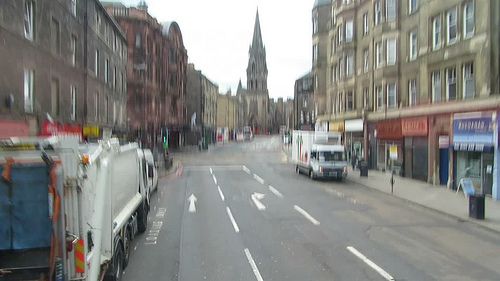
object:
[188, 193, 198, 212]
arrow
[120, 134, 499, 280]
road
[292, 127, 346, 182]
van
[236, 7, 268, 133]
building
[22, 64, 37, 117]
window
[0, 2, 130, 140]
building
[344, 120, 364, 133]
sign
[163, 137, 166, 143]
light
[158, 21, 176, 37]
roof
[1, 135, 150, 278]
truck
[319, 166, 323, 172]
headlight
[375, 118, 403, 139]
sign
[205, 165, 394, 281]
broken lines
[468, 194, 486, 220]
trash bin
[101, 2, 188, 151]
building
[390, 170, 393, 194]
parking meter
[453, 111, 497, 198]
storefront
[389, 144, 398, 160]
sign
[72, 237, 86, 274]
spiral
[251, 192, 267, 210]
arrow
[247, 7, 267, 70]
point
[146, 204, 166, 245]
word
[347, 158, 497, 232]
sidewalk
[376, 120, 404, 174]
store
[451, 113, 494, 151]
sign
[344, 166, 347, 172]
headlight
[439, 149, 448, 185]
door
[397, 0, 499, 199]
building